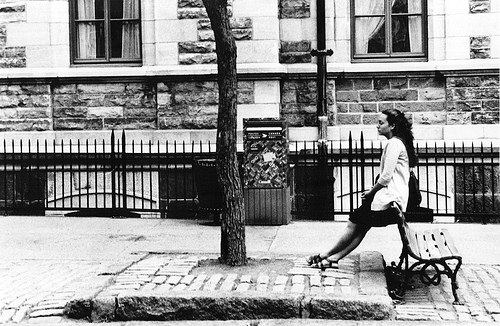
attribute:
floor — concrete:
[2, 207, 497, 323]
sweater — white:
[363, 131, 411, 225]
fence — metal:
[0, 131, 497, 233]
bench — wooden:
[389, 203, 472, 307]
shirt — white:
[379, 145, 419, 263]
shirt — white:
[302, 97, 427, 227]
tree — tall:
[183, 116, 251, 326]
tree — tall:
[193, 112, 252, 240]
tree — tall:
[213, 184, 250, 256]